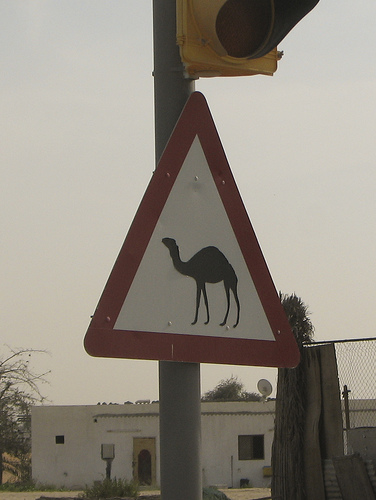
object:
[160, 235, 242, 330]
camel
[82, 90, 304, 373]
sign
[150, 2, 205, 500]
pole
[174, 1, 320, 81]
street light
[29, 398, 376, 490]
building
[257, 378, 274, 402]
satellite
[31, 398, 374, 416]
roof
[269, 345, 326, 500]
wood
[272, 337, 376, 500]
fence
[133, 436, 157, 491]
door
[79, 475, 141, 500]
bushes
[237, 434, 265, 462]
window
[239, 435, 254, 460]
curtain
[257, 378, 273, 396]
satellite dish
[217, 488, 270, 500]
sand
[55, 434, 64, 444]
square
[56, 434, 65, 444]
opening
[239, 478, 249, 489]
animal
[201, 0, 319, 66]
signal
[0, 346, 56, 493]
tree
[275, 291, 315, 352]
tree